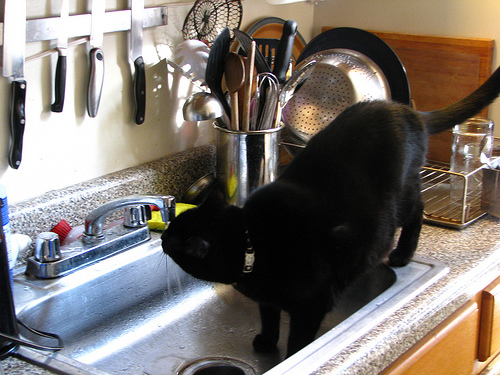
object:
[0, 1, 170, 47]
bar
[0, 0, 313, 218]
wall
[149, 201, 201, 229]
sponge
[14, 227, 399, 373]
sink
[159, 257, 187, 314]
water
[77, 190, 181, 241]
faucet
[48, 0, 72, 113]
knives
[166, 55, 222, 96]
utensils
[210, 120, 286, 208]
holder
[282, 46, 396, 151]
colander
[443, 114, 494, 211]
glass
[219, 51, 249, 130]
utensil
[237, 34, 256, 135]
utensil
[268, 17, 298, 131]
utensil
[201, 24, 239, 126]
utensil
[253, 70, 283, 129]
utensil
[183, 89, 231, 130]
utensil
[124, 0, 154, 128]
utensil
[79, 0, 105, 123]
utensil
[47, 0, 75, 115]
utensil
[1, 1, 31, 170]
implement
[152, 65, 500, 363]
cat